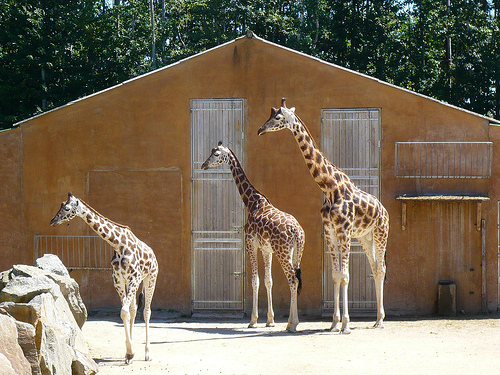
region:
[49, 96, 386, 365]
family of giraffes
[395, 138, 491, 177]
railing fixed to side of a building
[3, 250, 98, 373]
pile of boulders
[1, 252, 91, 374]
large rocks near giraffe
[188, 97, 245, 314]
three doors that open up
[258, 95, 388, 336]
male giraffe is lightly colored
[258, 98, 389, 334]
male has large horn on head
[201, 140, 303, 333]
female giraffe is darker colored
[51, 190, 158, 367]
adolecent male giraffe with horn on head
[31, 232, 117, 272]
railing fixed on side of building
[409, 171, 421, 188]
part of a wall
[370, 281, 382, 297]
part of a giraffe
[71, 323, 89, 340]
part of a rock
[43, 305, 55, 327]
edge of a rock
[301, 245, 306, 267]
tail of a giraffe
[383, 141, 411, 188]
part of a roof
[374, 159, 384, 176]
part of a house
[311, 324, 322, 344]
part of the ground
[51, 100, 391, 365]
Giraffes by the building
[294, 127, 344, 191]
The giraffe has a long neck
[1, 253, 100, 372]
Large stones by the small giraffe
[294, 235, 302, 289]
The tail of the giraffe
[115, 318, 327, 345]
A shadow on the ground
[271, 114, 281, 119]
The left eye of the giraffe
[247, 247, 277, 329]
The front legs of the giraffe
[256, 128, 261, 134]
The nose of the giraffe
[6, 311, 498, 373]
The ground below the giraffes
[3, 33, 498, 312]
A building behind the giraffes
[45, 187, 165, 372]
Small giraffe looking to the left side of the photo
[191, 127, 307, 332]
Medium sized giraffe to the left side of the photo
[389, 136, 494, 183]
Piece of metal bars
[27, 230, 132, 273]
Piece of metal bars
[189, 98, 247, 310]
Tall wooden door for giraffes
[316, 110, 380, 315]
Tall wooden door for giraffes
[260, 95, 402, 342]
Large giraffe looking toward the left of the photo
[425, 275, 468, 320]
Small stained metal box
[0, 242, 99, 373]
Pile of rocks on the left side of the photo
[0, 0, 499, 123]
Dark green trees above the building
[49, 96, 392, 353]
three giraffes standing by a building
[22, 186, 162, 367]
a giraffe standing by a big rock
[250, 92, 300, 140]
a head of a giraffe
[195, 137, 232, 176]
a head of a giraffe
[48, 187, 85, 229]
a head of a giraffe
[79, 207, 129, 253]
the neck of a giraffe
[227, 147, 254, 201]
the neck of a giraffe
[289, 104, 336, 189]
the neck of a giraffe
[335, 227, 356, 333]
the front leg of a giraffe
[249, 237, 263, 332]
the front leg of a giraffe